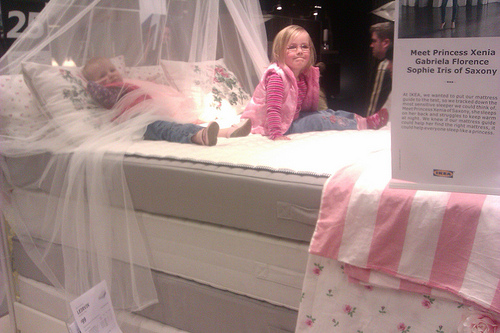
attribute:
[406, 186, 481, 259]
blanket — pink, white, striped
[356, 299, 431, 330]
blanket — white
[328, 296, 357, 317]
flowers — pink, little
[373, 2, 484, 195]
sign — white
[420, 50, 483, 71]
text — black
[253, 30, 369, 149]
girl — little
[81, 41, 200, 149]
girl — baby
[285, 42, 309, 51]
glasses — gold, girl's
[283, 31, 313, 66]
face — little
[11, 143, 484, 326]
mattresses — several, white, stacked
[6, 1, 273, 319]
canopy — white, gauzy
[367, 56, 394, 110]
jacket — striped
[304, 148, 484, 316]
blanket — striped, pink, white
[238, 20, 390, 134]
girl — little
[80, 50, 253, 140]
girl — little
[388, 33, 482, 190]
sign — ikea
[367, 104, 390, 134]
shoes — red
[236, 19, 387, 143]
girl — little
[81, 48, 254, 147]
girl — little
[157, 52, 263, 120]
pillow — floral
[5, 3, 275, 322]
fabric — sheer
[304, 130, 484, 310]
fabric — pink, striped, white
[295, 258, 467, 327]
fabric — pink, floral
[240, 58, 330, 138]
jacket — pink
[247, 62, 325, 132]
jacket — pink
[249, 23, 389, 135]
girl — little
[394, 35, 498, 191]
sign — Ikea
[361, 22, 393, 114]
man — profile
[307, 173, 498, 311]
blanket — pink, striped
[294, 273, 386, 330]
blanket — floral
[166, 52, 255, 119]
pillow — floral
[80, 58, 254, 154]
girl — little